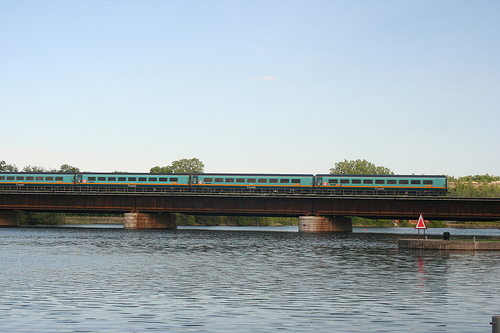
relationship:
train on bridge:
[1, 171, 447, 194] [2, 196, 499, 234]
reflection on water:
[417, 257, 426, 275] [0, 223, 499, 333]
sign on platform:
[415, 212, 428, 229] [397, 237, 499, 253]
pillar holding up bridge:
[123, 212, 178, 231] [2, 196, 499, 234]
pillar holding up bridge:
[298, 216, 354, 234] [2, 196, 499, 234]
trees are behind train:
[1, 161, 82, 173] [1, 171, 447, 194]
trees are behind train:
[150, 158, 204, 175] [1, 171, 447, 194]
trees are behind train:
[329, 158, 395, 177] [1, 171, 447, 194]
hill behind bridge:
[448, 176, 499, 196] [2, 196, 499, 234]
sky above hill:
[1, 0, 499, 179] [448, 176, 499, 196]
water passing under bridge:
[0, 223, 499, 333] [2, 196, 499, 234]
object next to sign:
[443, 231, 452, 242] [415, 212, 428, 229]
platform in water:
[397, 237, 499, 253] [0, 223, 499, 333]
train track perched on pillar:
[1, 194, 500, 220] [123, 212, 178, 231]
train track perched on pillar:
[1, 194, 500, 220] [298, 216, 354, 234]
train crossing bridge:
[1, 171, 447, 194] [2, 196, 499, 234]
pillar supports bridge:
[123, 212, 178, 231] [2, 196, 499, 234]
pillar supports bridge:
[298, 216, 354, 234] [2, 196, 499, 234]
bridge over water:
[2, 196, 499, 234] [0, 223, 499, 333]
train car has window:
[317, 176, 448, 191] [329, 179, 339, 185]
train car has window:
[317, 176, 448, 191] [340, 179, 351, 185]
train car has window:
[317, 176, 448, 191] [352, 178, 362, 184]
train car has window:
[317, 176, 448, 191] [363, 179, 375, 185]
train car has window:
[317, 176, 448, 191] [387, 179, 398, 185]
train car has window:
[80, 172, 191, 186] [88, 177, 97, 183]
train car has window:
[80, 172, 191, 186] [98, 176, 107, 183]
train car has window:
[80, 172, 191, 186] [108, 176, 117, 183]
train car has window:
[80, 172, 191, 186] [117, 177, 126, 182]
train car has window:
[80, 172, 191, 186] [169, 177, 179, 183]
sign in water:
[415, 212, 428, 229] [0, 223, 499, 333]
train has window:
[1, 171, 447, 194] [387, 179, 398, 185]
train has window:
[1, 171, 447, 194] [363, 179, 375, 185]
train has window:
[1, 171, 447, 194] [329, 179, 339, 185]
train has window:
[1, 171, 447, 194] [169, 177, 179, 183]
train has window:
[1, 171, 447, 194] [117, 177, 126, 182]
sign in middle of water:
[415, 212, 428, 229] [0, 223, 499, 333]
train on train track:
[1, 171, 447, 194] [1, 194, 500, 220]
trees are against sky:
[1, 161, 82, 173] [1, 0, 499, 179]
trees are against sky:
[150, 158, 204, 175] [1, 0, 499, 179]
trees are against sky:
[329, 158, 395, 177] [1, 0, 499, 179]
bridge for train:
[2, 196, 499, 234] [1, 171, 447, 194]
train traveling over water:
[1, 171, 447, 194] [0, 223, 499, 333]